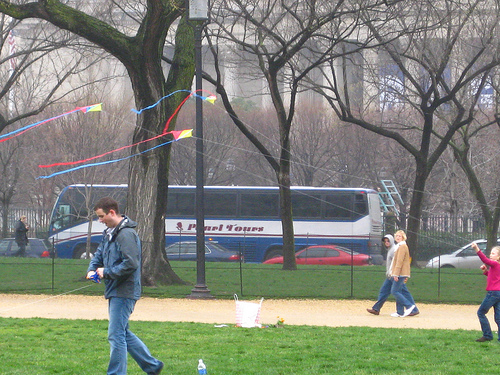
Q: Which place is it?
A: It is a park.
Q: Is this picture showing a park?
A: Yes, it is showing a park.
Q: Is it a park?
A: Yes, it is a park.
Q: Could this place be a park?
A: Yes, it is a park.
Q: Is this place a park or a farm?
A: It is a park.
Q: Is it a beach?
A: No, it is a park.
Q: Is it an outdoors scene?
A: Yes, it is outdoors.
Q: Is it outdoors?
A: Yes, it is outdoors.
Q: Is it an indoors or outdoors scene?
A: It is outdoors.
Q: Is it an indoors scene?
A: No, it is outdoors.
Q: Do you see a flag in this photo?
A: No, there are no flags.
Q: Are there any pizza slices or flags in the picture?
A: No, there are no flags or pizza slices.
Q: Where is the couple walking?
A: The couple is walking in the park.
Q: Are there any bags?
A: Yes, there is a bag.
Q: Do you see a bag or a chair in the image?
A: Yes, there is a bag.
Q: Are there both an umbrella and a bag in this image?
A: No, there is a bag but no umbrellas.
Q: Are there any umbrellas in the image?
A: No, there are no umbrellas.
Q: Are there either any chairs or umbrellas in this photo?
A: No, there are no umbrellas or chairs.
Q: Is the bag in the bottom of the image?
A: Yes, the bag is in the bottom of the image.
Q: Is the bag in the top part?
A: No, the bag is in the bottom of the image.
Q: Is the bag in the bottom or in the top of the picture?
A: The bag is in the bottom of the image.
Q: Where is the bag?
A: The bag is on the grass.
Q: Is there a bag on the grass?
A: Yes, there is a bag on the grass.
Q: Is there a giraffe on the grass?
A: No, there is a bag on the grass.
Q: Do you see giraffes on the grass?
A: No, there is a bag on the grass.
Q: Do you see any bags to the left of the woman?
A: Yes, there is a bag to the left of the woman.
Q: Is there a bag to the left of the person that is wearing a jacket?
A: Yes, there is a bag to the left of the woman.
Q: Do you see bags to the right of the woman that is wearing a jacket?
A: No, the bag is to the left of the woman.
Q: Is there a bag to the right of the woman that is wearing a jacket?
A: No, the bag is to the left of the woman.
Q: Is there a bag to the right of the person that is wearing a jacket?
A: No, the bag is to the left of the woman.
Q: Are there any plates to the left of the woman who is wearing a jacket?
A: No, there is a bag to the left of the woman.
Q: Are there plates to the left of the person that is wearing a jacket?
A: No, there is a bag to the left of the woman.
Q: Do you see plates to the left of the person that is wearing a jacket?
A: No, there is a bag to the left of the woman.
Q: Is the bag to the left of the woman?
A: Yes, the bag is to the left of the woman.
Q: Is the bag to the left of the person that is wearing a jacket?
A: Yes, the bag is to the left of the woman.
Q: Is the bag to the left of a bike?
A: No, the bag is to the left of the woman.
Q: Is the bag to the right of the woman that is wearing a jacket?
A: No, the bag is to the left of the woman.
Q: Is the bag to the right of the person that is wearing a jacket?
A: No, the bag is to the left of the woman.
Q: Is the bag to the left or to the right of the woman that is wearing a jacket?
A: The bag is to the left of the woman.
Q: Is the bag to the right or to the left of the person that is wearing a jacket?
A: The bag is to the left of the woman.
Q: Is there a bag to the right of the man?
A: Yes, there is a bag to the right of the man.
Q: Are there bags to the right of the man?
A: Yes, there is a bag to the right of the man.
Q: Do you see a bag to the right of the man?
A: Yes, there is a bag to the right of the man.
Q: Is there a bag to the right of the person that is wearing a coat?
A: Yes, there is a bag to the right of the man.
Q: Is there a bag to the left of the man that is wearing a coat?
A: No, the bag is to the right of the man.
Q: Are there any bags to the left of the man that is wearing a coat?
A: No, the bag is to the right of the man.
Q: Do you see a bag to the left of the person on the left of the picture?
A: No, the bag is to the right of the man.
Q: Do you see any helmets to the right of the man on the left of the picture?
A: No, there is a bag to the right of the man.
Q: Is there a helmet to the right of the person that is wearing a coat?
A: No, there is a bag to the right of the man.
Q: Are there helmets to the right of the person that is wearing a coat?
A: No, there is a bag to the right of the man.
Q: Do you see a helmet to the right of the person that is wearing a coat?
A: No, there is a bag to the right of the man.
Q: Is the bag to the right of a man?
A: Yes, the bag is to the right of a man.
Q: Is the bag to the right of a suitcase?
A: No, the bag is to the right of a man.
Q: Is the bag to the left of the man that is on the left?
A: No, the bag is to the right of the man.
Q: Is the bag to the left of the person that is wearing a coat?
A: No, the bag is to the right of the man.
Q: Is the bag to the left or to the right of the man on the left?
A: The bag is to the right of the man.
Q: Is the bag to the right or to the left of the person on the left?
A: The bag is to the right of the man.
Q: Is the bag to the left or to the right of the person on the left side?
A: The bag is to the right of the man.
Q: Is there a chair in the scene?
A: No, there are no chairs.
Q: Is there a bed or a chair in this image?
A: No, there are no chairs or beds.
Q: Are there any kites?
A: Yes, there is a kite.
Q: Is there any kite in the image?
A: Yes, there is a kite.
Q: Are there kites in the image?
A: Yes, there is a kite.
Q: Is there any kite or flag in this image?
A: Yes, there is a kite.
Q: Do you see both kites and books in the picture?
A: No, there is a kite but no books.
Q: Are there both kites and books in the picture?
A: No, there is a kite but no books.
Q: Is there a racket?
A: No, there are no rackets.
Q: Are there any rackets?
A: No, there are no rackets.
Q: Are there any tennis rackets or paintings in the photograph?
A: No, there are no tennis rackets or paintings.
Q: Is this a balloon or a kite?
A: This is a kite.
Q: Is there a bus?
A: Yes, there is a bus.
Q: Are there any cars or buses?
A: Yes, there is a bus.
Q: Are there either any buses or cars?
A: Yes, there is a bus.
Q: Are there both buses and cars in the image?
A: Yes, there are both a bus and a car.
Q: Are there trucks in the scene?
A: No, there are no trucks.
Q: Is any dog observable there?
A: Yes, there is a dog.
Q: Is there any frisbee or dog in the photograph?
A: Yes, there is a dog.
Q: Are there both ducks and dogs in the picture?
A: No, there is a dog but no ducks.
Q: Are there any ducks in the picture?
A: No, there are no ducks.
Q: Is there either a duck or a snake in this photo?
A: No, there are no ducks or snakes.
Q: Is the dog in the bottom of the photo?
A: Yes, the dog is in the bottom of the image.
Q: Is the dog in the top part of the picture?
A: No, the dog is in the bottom of the image.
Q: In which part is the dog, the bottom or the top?
A: The dog is in the bottom of the image.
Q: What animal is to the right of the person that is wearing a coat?
A: The animal is a dog.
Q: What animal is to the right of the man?
A: The animal is a dog.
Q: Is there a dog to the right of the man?
A: Yes, there is a dog to the right of the man.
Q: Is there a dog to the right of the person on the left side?
A: Yes, there is a dog to the right of the man.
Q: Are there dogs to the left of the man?
A: No, the dog is to the right of the man.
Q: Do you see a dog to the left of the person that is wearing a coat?
A: No, the dog is to the right of the man.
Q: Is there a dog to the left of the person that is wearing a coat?
A: No, the dog is to the right of the man.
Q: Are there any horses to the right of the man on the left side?
A: No, there is a dog to the right of the man.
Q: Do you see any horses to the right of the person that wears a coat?
A: No, there is a dog to the right of the man.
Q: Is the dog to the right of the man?
A: Yes, the dog is to the right of the man.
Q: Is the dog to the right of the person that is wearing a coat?
A: Yes, the dog is to the right of the man.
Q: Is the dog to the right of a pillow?
A: No, the dog is to the right of the man.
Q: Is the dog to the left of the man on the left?
A: No, the dog is to the right of the man.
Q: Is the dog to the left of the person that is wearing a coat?
A: No, the dog is to the right of the man.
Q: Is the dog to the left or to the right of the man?
A: The dog is to the right of the man.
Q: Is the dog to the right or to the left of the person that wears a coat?
A: The dog is to the right of the man.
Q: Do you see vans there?
A: No, there are no vans.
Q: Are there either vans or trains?
A: No, there are no vans or trains.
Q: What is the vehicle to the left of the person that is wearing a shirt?
A: The vehicle is a car.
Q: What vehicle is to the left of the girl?
A: The vehicle is a car.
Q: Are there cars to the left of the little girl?
A: Yes, there is a car to the left of the girl.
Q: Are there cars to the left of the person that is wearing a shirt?
A: Yes, there is a car to the left of the girl.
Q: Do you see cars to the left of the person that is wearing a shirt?
A: Yes, there is a car to the left of the girl.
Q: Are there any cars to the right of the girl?
A: No, the car is to the left of the girl.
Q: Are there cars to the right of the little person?
A: No, the car is to the left of the girl.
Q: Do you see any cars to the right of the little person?
A: No, the car is to the left of the girl.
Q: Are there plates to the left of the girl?
A: No, there is a car to the left of the girl.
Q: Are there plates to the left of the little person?
A: No, there is a car to the left of the girl.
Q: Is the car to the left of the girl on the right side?
A: Yes, the car is to the left of the girl.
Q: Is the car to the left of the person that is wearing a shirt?
A: Yes, the car is to the left of the girl.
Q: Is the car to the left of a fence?
A: No, the car is to the left of the girl.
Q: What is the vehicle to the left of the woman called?
A: The vehicle is a car.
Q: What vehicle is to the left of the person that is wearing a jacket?
A: The vehicle is a car.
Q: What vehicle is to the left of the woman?
A: The vehicle is a car.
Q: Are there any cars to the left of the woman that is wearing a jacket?
A: Yes, there is a car to the left of the woman.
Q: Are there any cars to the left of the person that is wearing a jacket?
A: Yes, there is a car to the left of the woman.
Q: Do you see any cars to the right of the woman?
A: No, the car is to the left of the woman.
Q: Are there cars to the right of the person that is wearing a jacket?
A: No, the car is to the left of the woman.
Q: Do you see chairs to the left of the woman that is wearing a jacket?
A: No, there is a car to the left of the woman.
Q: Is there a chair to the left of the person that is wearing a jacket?
A: No, there is a car to the left of the woman.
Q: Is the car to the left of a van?
A: No, the car is to the left of the woman.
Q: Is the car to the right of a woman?
A: No, the car is to the left of a woman.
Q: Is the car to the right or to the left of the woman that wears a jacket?
A: The car is to the left of the woman.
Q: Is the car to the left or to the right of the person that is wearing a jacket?
A: The car is to the left of the woman.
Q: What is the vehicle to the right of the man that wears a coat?
A: The vehicle is a car.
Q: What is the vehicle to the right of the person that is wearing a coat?
A: The vehicle is a car.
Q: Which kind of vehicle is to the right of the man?
A: The vehicle is a car.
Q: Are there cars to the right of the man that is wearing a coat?
A: Yes, there is a car to the right of the man.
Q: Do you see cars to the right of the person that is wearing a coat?
A: Yes, there is a car to the right of the man.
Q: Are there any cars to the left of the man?
A: No, the car is to the right of the man.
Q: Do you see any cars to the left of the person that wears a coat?
A: No, the car is to the right of the man.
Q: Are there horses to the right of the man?
A: No, there is a car to the right of the man.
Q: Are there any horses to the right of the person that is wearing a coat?
A: No, there is a car to the right of the man.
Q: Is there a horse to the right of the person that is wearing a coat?
A: No, there is a car to the right of the man.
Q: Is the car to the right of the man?
A: Yes, the car is to the right of the man.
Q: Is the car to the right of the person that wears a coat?
A: Yes, the car is to the right of the man.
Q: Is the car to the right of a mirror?
A: No, the car is to the right of the man.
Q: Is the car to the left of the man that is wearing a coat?
A: No, the car is to the right of the man.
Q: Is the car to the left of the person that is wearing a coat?
A: No, the car is to the right of the man.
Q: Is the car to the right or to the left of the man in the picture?
A: The car is to the right of the man.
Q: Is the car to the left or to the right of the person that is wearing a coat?
A: The car is to the right of the man.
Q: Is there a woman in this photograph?
A: Yes, there is a woman.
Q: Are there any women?
A: Yes, there is a woman.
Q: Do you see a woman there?
A: Yes, there is a woman.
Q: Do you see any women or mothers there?
A: Yes, there is a woman.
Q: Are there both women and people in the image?
A: Yes, there are both a woman and people.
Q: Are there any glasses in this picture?
A: No, there are no glasses.